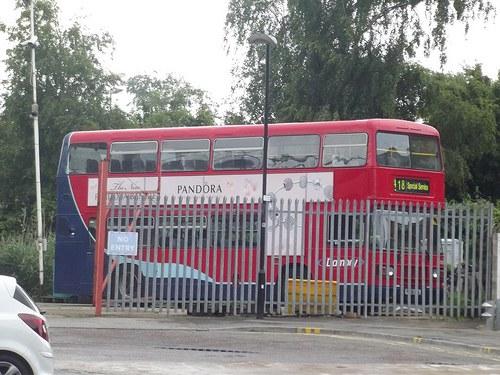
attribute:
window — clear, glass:
[320, 128, 359, 167]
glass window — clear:
[264, 133, 316, 164]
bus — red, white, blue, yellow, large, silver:
[54, 118, 446, 316]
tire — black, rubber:
[275, 262, 314, 302]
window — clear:
[161, 139, 212, 174]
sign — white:
[85, 172, 335, 204]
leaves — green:
[307, 89, 322, 99]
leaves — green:
[360, 80, 376, 94]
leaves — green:
[349, 44, 367, 64]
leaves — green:
[449, 152, 459, 172]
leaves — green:
[457, 122, 477, 142]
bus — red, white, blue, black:
[39, 109, 451, 326]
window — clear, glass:
[209, 134, 263, 170]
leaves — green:
[61, 87, 199, 126]